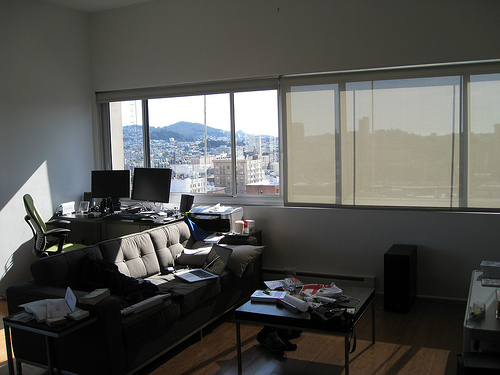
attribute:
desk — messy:
[55, 201, 248, 246]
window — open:
[91, 55, 499, 216]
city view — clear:
[117, 103, 282, 199]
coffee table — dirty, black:
[231, 274, 379, 374]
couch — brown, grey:
[4, 217, 265, 374]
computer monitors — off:
[90, 166, 174, 204]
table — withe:
[464, 266, 500, 357]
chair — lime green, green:
[22, 193, 89, 259]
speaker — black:
[382, 242, 419, 314]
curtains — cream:
[280, 57, 498, 215]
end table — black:
[1, 301, 101, 375]